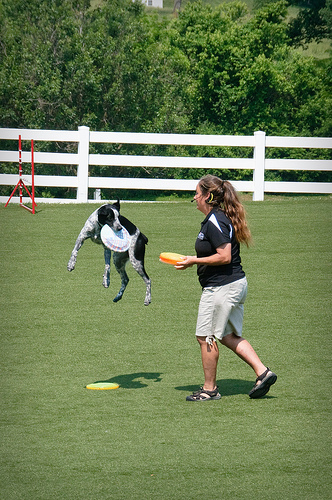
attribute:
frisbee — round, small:
[97, 221, 133, 258]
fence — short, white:
[0, 123, 331, 211]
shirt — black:
[193, 205, 245, 290]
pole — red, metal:
[29, 138, 35, 212]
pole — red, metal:
[17, 134, 23, 205]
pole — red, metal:
[20, 203, 35, 213]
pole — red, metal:
[3, 180, 19, 207]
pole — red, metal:
[20, 179, 37, 206]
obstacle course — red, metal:
[3, 134, 39, 213]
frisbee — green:
[87, 381, 124, 399]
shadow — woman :
[98, 364, 161, 401]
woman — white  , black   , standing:
[166, 170, 279, 413]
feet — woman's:
[186, 370, 276, 401]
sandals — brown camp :
[184, 363, 283, 406]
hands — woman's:
[174, 253, 195, 274]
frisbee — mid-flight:
[94, 217, 139, 258]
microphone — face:
[187, 196, 214, 204]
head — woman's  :
[189, 172, 230, 216]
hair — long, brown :
[199, 173, 255, 244]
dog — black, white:
[63, 197, 158, 309]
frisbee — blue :
[100, 224, 131, 252]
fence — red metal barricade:
[6, 118, 321, 209]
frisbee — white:
[98, 225, 134, 255]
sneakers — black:
[181, 369, 279, 405]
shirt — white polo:
[195, 211, 248, 287]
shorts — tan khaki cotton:
[193, 276, 249, 340]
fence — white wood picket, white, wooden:
[2, 121, 320, 203]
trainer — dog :
[156, 177, 275, 409]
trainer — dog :
[177, 169, 282, 397]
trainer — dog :
[165, 175, 280, 406]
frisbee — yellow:
[86, 377, 122, 396]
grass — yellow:
[3, 202, 319, 488]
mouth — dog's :
[105, 218, 125, 232]